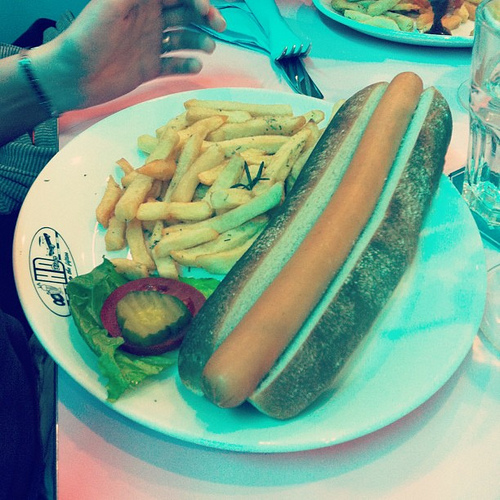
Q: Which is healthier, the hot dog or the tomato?
A: The tomato is healthier than the hot dog.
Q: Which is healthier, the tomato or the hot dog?
A: The tomato is healthier than the hot dog.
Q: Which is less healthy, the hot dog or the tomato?
A: The hot dog is less healthy than the tomato.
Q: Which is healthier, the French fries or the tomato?
A: The tomato is healthier than the French fries.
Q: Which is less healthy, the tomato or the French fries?
A: The French fries is less healthy than the tomato.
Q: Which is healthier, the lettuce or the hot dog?
A: The lettuce is healthier than the hot dog.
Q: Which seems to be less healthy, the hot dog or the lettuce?
A: The hot dog is less healthy than the lettuce.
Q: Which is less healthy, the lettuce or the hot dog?
A: The hot dog is less healthy than the lettuce.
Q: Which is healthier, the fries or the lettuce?
A: The lettuce is healthier than the fries.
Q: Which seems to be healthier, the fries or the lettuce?
A: The lettuce is healthier than the fries.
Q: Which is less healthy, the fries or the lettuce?
A: The fries is less healthy than the lettuce.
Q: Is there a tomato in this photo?
A: Yes, there is a tomato.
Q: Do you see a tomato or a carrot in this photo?
A: Yes, there is a tomato.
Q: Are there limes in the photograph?
A: No, there are no limes.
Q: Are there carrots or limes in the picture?
A: No, there are no limes or carrots.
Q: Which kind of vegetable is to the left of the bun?
A: The vegetable is a tomato.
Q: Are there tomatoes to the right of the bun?
A: No, the tomato is to the left of the bun.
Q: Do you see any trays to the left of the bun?
A: No, there is a tomato to the left of the bun.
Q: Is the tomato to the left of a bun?
A: Yes, the tomato is to the left of a bun.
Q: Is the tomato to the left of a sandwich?
A: No, the tomato is to the left of a bun.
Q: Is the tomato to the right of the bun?
A: No, the tomato is to the left of the bun.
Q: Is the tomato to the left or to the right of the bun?
A: The tomato is to the left of the bun.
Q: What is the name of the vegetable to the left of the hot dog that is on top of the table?
A: The vegetable is a tomato.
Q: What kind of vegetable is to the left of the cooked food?
A: The vegetable is a tomato.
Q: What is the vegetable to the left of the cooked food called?
A: The vegetable is a tomato.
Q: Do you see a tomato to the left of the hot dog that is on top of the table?
A: Yes, there is a tomato to the left of the hot dog.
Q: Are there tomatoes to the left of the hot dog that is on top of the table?
A: Yes, there is a tomato to the left of the hot dog.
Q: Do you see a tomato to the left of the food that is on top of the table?
A: Yes, there is a tomato to the left of the hot dog.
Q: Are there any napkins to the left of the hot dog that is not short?
A: No, there is a tomato to the left of the hot dog.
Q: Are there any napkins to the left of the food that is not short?
A: No, there is a tomato to the left of the hot dog.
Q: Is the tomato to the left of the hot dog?
A: Yes, the tomato is to the left of the hot dog.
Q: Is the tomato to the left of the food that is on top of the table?
A: Yes, the tomato is to the left of the hot dog.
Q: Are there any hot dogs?
A: Yes, there is a hot dog.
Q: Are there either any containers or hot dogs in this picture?
A: Yes, there is a hot dog.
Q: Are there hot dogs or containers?
A: Yes, there is a hot dog.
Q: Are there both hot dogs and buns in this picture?
A: Yes, there are both a hot dog and a bun.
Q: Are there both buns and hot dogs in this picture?
A: Yes, there are both a hot dog and a bun.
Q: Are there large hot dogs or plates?
A: Yes, there is a large hot dog.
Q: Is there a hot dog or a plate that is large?
A: Yes, the hot dog is large.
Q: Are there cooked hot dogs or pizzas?
A: Yes, there is a cooked hot dog.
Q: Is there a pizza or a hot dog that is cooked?
A: Yes, the hot dog is cooked.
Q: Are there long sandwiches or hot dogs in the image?
A: Yes, there is a long hot dog.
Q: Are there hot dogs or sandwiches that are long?
A: Yes, the hot dog is long.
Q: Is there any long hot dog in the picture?
A: Yes, there is a long hot dog.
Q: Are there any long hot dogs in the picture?
A: Yes, there is a long hot dog.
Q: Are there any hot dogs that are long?
A: Yes, there is a hot dog that is long.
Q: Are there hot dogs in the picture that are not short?
A: Yes, there is a long hot dog.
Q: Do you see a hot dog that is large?
A: Yes, there is a large hot dog.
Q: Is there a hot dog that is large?
A: Yes, there is a hot dog that is large.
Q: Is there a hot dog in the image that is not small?
A: Yes, there is a large hot dog.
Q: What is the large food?
A: The food is a hot dog.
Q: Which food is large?
A: The food is a hot dog.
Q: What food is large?
A: The food is a hot dog.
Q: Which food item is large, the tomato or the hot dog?
A: The hot dog is large.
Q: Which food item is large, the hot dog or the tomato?
A: The hot dog is large.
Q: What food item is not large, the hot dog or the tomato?
A: The tomato is not large.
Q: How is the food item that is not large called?
A: The food item is a tomato.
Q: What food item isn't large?
A: The food item is a tomato.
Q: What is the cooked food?
A: The food is a hot dog.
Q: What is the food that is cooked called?
A: The food is a hot dog.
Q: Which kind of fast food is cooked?
A: The fast food is a hot dog.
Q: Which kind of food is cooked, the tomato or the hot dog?
A: The hot dog is cooked.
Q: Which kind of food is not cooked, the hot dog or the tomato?
A: The tomato is not cooked.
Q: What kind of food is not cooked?
A: The food is a tomato.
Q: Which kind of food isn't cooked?
A: The food is a tomato.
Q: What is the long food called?
A: The food is a hot dog.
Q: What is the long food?
A: The food is a hot dog.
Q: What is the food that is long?
A: The food is a hot dog.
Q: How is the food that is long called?
A: The food is a hot dog.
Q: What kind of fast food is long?
A: The fast food is a hot dog.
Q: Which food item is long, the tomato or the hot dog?
A: The hot dog is long.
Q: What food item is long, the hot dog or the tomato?
A: The hot dog is long.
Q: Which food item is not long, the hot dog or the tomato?
A: The tomato is not long.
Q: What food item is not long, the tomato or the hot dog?
A: The tomato is not long.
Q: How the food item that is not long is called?
A: The food item is a tomato.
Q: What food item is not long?
A: The food item is a tomato.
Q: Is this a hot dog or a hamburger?
A: This is a hot dog.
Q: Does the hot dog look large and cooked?
A: Yes, the hot dog is large and cooked.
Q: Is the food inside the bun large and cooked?
A: Yes, the hot dog is large and cooked.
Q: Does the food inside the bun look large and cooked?
A: Yes, the hot dog is large and cooked.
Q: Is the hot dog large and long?
A: Yes, the hot dog is large and long.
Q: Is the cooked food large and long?
A: Yes, the hot dog is large and long.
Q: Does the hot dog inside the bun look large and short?
A: No, the hot dog is large but long.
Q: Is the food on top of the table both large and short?
A: No, the hot dog is large but long.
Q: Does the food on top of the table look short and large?
A: No, the hot dog is large but long.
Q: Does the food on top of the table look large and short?
A: No, the hot dog is large but long.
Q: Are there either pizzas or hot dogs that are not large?
A: No, there is a hot dog but it is large.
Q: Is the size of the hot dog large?
A: Yes, the hot dog is large.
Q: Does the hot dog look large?
A: Yes, the hot dog is large.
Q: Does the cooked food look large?
A: Yes, the hot dog is large.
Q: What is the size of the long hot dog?
A: The hot dog is large.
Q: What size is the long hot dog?
A: The hot dog is large.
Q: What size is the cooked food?
A: The hot dog is large.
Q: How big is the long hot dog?
A: The hot dog is large.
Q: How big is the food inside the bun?
A: The hot dog is large.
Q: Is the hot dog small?
A: No, the hot dog is large.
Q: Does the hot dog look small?
A: No, the hot dog is large.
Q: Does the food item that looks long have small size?
A: No, the hot dog is large.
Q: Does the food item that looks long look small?
A: No, the hot dog is large.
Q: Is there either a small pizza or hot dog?
A: No, there is a hot dog but it is large.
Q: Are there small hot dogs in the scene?
A: No, there is a hot dog but it is large.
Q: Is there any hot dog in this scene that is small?
A: No, there is a hot dog but it is large.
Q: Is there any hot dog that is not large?
A: No, there is a hot dog but it is large.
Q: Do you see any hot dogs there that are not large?
A: No, there is a hot dog but it is large.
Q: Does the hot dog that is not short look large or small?
A: The hot dog is large.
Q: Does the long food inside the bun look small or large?
A: The hot dog is large.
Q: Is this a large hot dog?
A: Yes, this is a large hot dog.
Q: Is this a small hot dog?
A: No, this is a large hot dog.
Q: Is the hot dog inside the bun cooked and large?
A: Yes, the hot dog is cooked and large.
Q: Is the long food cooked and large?
A: Yes, the hot dog is cooked and large.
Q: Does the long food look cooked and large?
A: Yes, the hot dog is cooked and large.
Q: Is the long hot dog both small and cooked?
A: No, the hot dog is cooked but large.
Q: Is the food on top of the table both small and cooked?
A: No, the hot dog is cooked but large.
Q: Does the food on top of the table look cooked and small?
A: No, the hot dog is cooked but large.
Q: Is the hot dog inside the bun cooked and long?
A: Yes, the hot dog is cooked and long.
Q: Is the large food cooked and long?
A: Yes, the hot dog is cooked and long.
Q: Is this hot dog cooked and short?
A: No, the hot dog is cooked but long.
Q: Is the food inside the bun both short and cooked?
A: No, the hot dog is cooked but long.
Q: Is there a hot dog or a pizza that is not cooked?
A: No, there is a hot dog but it is cooked.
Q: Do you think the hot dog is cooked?
A: Yes, the hot dog is cooked.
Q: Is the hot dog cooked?
A: Yes, the hot dog is cooked.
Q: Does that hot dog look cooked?
A: Yes, the hot dog is cooked.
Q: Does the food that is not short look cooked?
A: Yes, the hot dog is cooked.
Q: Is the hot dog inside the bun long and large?
A: Yes, the hot dog is long and large.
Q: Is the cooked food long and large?
A: Yes, the hot dog is long and large.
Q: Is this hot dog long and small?
A: No, the hot dog is long but large.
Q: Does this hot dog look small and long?
A: No, the hot dog is long but large.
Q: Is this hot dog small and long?
A: No, the hot dog is long but large.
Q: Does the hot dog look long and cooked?
A: Yes, the hot dog is long and cooked.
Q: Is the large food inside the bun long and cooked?
A: Yes, the hot dog is long and cooked.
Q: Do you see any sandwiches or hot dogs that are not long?
A: No, there is a hot dog but it is long.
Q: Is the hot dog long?
A: Yes, the hot dog is long.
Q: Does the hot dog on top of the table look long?
A: Yes, the hot dog is long.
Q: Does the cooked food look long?
A: Yes, the hot dog is long.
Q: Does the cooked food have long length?
A: Yes, the hot dog is long.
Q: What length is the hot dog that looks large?
A: The hot dog is long.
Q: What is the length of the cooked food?
A: The hot dog is long.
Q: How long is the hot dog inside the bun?
A: The hot dog is long.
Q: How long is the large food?
A: The hot dog is long.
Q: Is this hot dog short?
A: No, the hot dog is long.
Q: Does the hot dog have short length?
A: No, the hot dog is long.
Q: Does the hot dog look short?
A: No, the hot dog is long.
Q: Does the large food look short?
A: No, the hot dog is long.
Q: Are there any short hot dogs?
A: No, there is a hot dog but it is long.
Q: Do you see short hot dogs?
A: No, there is a hot dog but it is long.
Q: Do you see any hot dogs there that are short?
A: No, there is a hot dog but it is long.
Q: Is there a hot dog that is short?
A: No, there is a hot dog but it is long.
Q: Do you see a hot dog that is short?
A: No, there is a hot dog but it is long.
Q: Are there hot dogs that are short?
A: No, there is a hot dog but it is long.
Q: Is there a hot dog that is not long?
A: No, there is a hot dog but it is long.